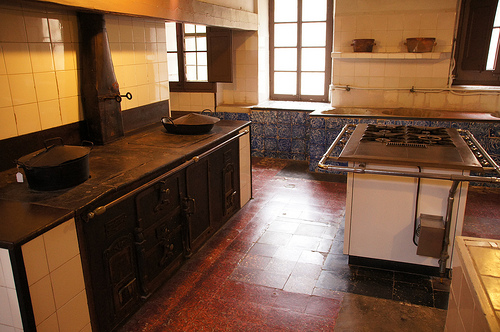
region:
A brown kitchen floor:
[165, 271, 260, 324]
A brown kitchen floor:
[265, 160, 343, 217]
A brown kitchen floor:
[472, 185, 497, 230]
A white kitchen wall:
[20, 23, 91, 113]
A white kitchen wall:
[350, 0, 446, 35]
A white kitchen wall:
[37, 258, 87, 323]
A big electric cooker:
[332, 103, 435, 283]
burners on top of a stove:
[361, 124, 454, 149]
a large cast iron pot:
[14, 136, 96, 188]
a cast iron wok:
[157, 105, 224, 135]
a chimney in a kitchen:
[77, 13, 132, 140]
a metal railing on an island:
[314, 159, 499, 184]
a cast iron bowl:
[350, 35, 375, 52]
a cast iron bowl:
[402, 35, 439, 51]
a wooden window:
[267, 1, 330, 103]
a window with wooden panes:
[181, 24, 206, 83]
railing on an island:
[318, 121, 349, 171]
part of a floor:
[262, 250, 267, 266]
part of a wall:
[343, 63, 357, 96]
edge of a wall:
[67, 95, 83, 119]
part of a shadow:
[279, 220, 292, 275]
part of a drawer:
[158, 202, 172, 253]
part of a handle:
[156, 223, 176, 233]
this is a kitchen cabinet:
[184, 158, 254, 216]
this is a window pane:
[271, 67, 296, 95]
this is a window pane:
[297, 70, 331, 98]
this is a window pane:
[274, 44, 300, 69]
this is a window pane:
[298, 44, 328, 67]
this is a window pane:
[274, 21, 299, 44]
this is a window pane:
[298, 19, 328, 45]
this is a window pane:
[274, 2, 297, 25]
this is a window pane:
[301, 2, 328, 19]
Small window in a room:
[267, 69, 303, 101]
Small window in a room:
[300, 72, 328, 98]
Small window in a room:
[297, 43, 328, 70]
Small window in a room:
[300, 23, 327, 43]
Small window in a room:
[299, 1, 331, 22]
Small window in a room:
[269, 3, 296, 20]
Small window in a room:
[268, 20, 299, 41]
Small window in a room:
[271, 45, 299, 71]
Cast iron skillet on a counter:
[8, 136, 113, 198]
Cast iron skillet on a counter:
[155, 93, 242, 161]